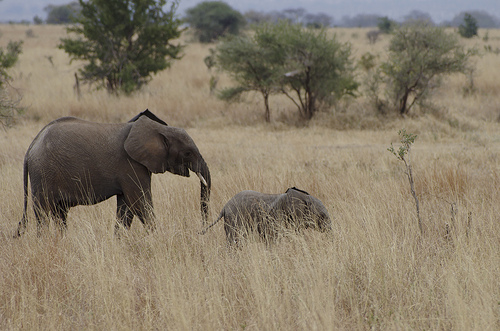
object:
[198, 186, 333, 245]
baby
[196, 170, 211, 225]
trunk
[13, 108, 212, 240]
elephant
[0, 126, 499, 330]
grass